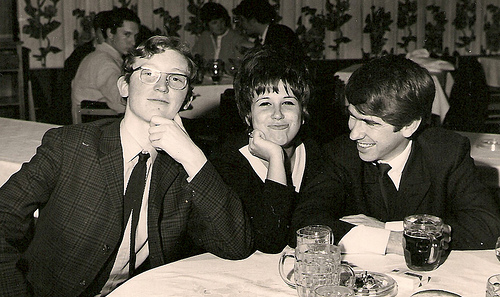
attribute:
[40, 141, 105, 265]
suit — striped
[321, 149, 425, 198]
suit — black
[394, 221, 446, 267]
glass — drinking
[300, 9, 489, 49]
curtains — floral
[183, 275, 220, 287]
tablecloth — white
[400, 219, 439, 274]
beverage — glass